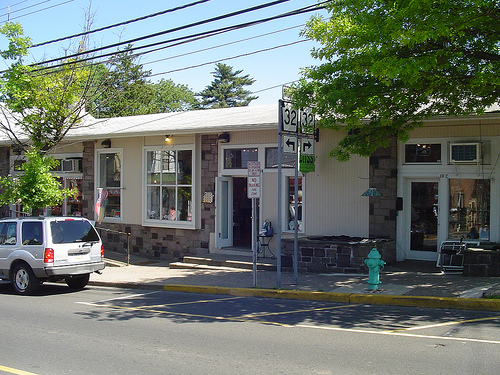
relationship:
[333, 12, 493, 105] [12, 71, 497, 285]
tree next to building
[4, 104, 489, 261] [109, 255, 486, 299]
long house on sidewalk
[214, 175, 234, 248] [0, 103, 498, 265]
door of building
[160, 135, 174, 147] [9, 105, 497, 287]
light bulb outside building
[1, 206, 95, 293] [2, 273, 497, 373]
car on roadside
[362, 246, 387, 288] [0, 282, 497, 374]
hydrant beside road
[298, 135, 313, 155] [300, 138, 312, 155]
sign with arrow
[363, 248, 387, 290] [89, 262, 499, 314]
hydrant on sidewalk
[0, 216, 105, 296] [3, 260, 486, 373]
car on road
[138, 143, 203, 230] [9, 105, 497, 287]
window on building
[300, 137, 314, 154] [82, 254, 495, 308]
sign on sidewalk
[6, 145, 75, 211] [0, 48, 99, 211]
leaves on tree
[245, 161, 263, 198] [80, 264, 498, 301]
sign on sidewalk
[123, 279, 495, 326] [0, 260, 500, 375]
lines on road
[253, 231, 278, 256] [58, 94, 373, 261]
table outside building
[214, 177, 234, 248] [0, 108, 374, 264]
door on building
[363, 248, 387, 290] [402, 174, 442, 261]
hydrant in front of door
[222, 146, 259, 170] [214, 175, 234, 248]
window above door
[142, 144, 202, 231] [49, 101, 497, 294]
window on building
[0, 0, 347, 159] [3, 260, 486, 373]
power lines above road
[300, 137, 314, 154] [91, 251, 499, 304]
sign on sidewalk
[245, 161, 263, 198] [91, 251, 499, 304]
sign on sidewalk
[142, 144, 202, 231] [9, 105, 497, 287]
window on building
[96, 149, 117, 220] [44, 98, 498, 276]
window on building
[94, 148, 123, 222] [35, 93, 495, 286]
window on building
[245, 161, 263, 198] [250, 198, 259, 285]
sign on pole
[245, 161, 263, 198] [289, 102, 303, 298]
sign on pole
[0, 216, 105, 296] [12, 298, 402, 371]
car on street